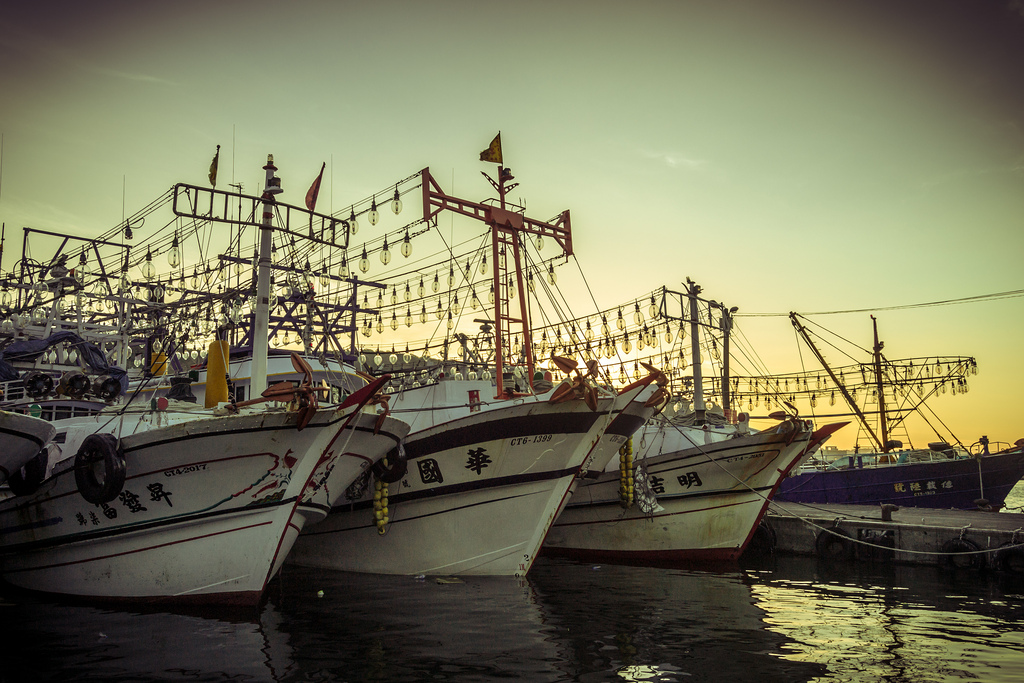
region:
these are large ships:
[73, 51, 927, 536]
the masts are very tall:
[160, 130, 777, 416]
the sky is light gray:
[570, 98, 903, 261]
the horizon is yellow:
[728, 288, 1020, 516]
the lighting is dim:
[122, 113, 604, 513]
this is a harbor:
[213, 446, 847, 618]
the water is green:
[555, 572, 739, 668]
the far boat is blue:
[798, 435, 1017, 519]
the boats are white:
[9, 285, 873, 675]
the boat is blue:
[783, 402, 1021, 565]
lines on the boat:
[3, 411, 416, 582]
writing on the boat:
[394, 423, 530, 506]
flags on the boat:
[163, 124, 348, 223]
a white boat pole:
[173, 149, 314, 412]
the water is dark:
[49, 529, 1015, 679]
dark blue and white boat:
[768, 433, 1022, 510]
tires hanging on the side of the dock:
[753, 525, 1022, 580]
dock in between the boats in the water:
[757, 502, 1021, 572]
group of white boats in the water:
[0, 136, 848, 599]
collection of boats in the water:
[0, 127, 1021, 599]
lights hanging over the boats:
[0, 165, 985, 423]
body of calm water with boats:
[0, 546, 1018, 680]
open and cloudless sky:
[0, 0, 1019, 452]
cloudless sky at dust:
[0, 1, 1022, 477]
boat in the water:
[678, 397, 821, 584]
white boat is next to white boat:
[543, 417, 848, 568]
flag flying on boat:
[479, 132, 505, 166]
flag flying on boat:
[203, 140, 221, 195]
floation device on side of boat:
[67, 432, 130, 503]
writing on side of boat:
[458, 440, 492, 479]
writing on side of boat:
[668, 464, 710, 493]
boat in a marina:
[5, 154, 407, 616]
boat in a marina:
[290, 116, 682, 576]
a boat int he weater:
[327, 335, 575, 665]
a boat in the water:
[839, 358, 991, 556]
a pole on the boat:
[763, 265, 938, 490]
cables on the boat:
[725, 285, 938, 466]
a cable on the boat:
[555, 241, 762, 407]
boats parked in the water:
[3, 359, 1021, 615]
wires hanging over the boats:
[0, 121, 1022, 458]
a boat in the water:
[4, 347, 406, 630]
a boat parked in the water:
[288, 372, 666, 601]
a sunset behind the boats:
[6, 153, 1022, 461]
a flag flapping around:
[469, 115, 524, 223]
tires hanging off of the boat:
[3, 431, 136, 515]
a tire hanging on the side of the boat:
[364, 432, 415, 490]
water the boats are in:
[0, 536, 1021, 680]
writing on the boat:
[70, 473, 181, 535]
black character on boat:
[132, 476, 183, 514]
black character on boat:
[108, 483, 150, 516]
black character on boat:
[97, 502, 118, 518]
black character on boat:
[87, 505, 103, 529]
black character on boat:
[467, 437, 496, 486]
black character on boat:
[410, 451, 448, 491]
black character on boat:
[669, 462, 704, 494]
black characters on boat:
[70, 477, 179, 529]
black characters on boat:
[416, 443, 503, 497]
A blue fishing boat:
[770, 313, 1021, 511]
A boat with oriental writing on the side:
[0, 152, 409, 612]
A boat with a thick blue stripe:
[302, 127, 658, 586]